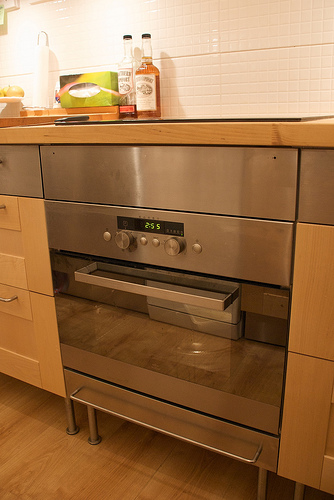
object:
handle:
[73, 261, 240, 312]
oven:
[43, 201, 294, 474]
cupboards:
[275, 221, 333, 494]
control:
[164, 238, 181, 256]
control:
[115, 232, 130, 250]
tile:
[220, 54, 275, 106]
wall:
[0, 0, 334, 118]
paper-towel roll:
[26, 31, 58, 108]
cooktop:
[0, 118, 331, 125]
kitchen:
[0, 0, 334, 500]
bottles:
[117, 34, 160, 118]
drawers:
[0, 193, 65, 400]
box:
[60, 71, 122, 109]